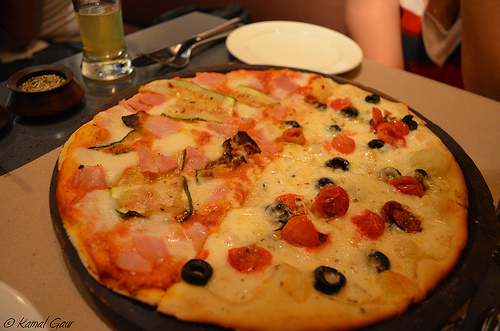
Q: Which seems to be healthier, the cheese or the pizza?
A: The cheese is healthier than the pizza.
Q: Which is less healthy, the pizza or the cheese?
A: The pizza is less healthy than the cheese.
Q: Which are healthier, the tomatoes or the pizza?
A: The tomatoes are healthier than the pizza.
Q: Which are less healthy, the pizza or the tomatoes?
A: The pizza are less healthy than the tomatoes.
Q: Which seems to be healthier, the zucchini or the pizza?
A: The zucchini is healthier than the pizza.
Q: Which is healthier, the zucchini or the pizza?
A: The zucchini is healthier than the pizza.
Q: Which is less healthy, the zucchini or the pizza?
A: The pizza is less healthy than the zucchini.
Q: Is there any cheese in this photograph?
A: Yes, there is cheese.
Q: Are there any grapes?
A: No, there are no grapes.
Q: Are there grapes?
A: No, there are no grapes.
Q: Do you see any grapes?
A: No, there are no grapes.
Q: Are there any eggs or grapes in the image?
A: No, there are no grapes or eggs.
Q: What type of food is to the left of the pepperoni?
A: The food is cheese.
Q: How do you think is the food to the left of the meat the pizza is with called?
A: The food is cheese.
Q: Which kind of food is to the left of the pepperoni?
A: The food is cheese.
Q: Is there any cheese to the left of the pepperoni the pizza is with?
A: Yes, there is cheese to the left of the pepperoni.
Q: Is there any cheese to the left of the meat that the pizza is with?
A: Yes, there is cheese to the left of the pepperoni.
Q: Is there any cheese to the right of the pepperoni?
A: No, the cheese is to the left of the pepperoni.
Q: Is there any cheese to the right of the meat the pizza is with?
A: No, the cheese is to the left of the pepperoni.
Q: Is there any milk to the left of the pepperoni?
A: No, there is cheese to the left of the pepperoni.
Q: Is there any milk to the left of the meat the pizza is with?
A: No, there is cheese to the left of the pepperoni.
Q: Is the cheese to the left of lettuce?
A: No, the cheese is to the left of the pepperoni.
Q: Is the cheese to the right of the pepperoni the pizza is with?
A: No, the cheese is to the left of the pepperoni.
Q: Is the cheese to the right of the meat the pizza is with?
A: No, the cheese is to the left of the pepperoni.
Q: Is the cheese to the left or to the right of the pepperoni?
A: The cheese is to the left of the pepperoni.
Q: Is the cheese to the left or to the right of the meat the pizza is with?
A: The cheese is to the left of the pepperoni.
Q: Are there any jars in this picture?
A: No, there are no jars.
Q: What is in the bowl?
A: The condiments are in the bowl.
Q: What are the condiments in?
A: The condiments are in the bowl.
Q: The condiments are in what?
A: The condiments are in the bowl.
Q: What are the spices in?
A: The condiments are in the bowl.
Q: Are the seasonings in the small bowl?
A: Yes, the seasonings are in the bowl.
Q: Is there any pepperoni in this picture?
A: Yes, there is pepperoni.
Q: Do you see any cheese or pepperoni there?
A: Yes, there is pepperoni.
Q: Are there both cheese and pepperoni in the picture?
A: Yes, there are both pepperoni and cheese.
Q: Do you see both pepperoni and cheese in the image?
A: Yes, there are both pepperoni and cheese.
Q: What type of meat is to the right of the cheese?
A: The meat is pepperoni.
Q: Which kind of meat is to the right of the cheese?
A: The meat is pepperoni.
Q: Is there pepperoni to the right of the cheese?
A: Yes, there is pepperoni to the right of the cheese.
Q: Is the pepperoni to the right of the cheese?
A: Yes, the pepperoni is to the right of the cheese.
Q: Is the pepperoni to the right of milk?
A: No, the pepperoni is to the right of the cheese.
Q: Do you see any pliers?
A: No, there are no pliers.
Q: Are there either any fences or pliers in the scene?
A: No, there are no pliers or fences.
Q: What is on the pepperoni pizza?
A: The toppings are on the pizza.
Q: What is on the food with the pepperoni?
A: The toppings are on the pizza.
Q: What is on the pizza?
A: The toppings are on the pizza.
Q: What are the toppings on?
A: The toppings are on the pizza.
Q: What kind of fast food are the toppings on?
A: The toppings are on the pizza.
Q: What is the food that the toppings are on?
A: The food is a pizza.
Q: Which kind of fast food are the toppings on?
A: The toppings are on the pizza.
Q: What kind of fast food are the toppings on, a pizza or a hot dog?
A: The toppings are on a pizza.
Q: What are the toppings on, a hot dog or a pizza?
A: The toppings are on a pizza.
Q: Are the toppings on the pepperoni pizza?
A: Yes, the toppings are on the pizza.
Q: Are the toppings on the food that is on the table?
A: Yes, the toppings are on the pizza.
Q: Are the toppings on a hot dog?
A: No, the toppings are on the pizza.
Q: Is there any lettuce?
A: No, there is no lettuce.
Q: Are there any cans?
A: No, there are no cans.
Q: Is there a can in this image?
A: No, there are no cans.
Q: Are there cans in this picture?
A: No, there are no cans.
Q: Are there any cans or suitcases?
A: No, there are no cans or suitcases.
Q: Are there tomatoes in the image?
A: Yes, there are tomatoes.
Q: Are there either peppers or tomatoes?
A: Yes, there are tomatoes.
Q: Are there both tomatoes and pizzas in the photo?
A: Yes, there are both tomatoes and a pizza.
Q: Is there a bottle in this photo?
A: No, there are no bottles.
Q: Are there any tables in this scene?
A: Yes, there is a table.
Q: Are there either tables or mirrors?
A: Yes, there is a table.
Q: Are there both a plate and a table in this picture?
A: Yes, there are both a table and a plate.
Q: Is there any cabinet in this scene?
A: No, there are no cabinets.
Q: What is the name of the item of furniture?
A: The piece of furniture is a table.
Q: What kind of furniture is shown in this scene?
A: The furniture is a table.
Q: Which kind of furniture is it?
A: The piece of furniture is a table.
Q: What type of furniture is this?
A: That is a table.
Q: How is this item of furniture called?
A: That is a table.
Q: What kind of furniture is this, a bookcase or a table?
A: That is a table.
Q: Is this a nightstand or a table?
A: This is a table.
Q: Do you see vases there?
A: No, there are no vases.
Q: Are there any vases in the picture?
A: No, there are no vases.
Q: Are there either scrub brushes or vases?
A: No, there are no vases or scrub brushes.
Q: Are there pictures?
A: No, there are no pictures.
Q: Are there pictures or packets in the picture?
A: No, there are no pictures or packets.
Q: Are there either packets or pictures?
A: No, there are no pictures or packets.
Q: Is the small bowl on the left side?
A: Yes, the bowl is on the left of the image.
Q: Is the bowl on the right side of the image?
A: No, the bowl is on the left of the image.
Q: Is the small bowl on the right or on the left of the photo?
A: The bowl is on the left of the image.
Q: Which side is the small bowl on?
A: The bowl is on the left of the image.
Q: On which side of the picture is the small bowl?
A: The bowl is on the left of the image.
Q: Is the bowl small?
A: Yes, the bowl is small.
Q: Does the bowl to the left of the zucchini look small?
A: Yes, the bowl is small.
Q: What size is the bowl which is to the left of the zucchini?
A: The bowl is small.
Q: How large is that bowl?
A: The bowl is small.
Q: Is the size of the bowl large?
A: No, the bowl is small.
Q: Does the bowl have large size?
A: No, the bowl is small.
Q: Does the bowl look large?
A: No, the bowl is small.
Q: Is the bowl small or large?
A: The bowl is small.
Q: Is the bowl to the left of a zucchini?
A: Yes, the bowl is to the left of a zucchini.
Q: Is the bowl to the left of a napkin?
A: No, the bowl is to the left of a zucchini.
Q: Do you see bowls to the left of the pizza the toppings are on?
A: Yes, there is a bowl to the left of the pizza.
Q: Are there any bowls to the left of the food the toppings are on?
A: Yes, there is a bowl to the left of the pizza.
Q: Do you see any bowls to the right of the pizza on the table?
A: No, the bowl is to the left of the pizza.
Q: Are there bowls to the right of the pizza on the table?
A: No, the bowl is to the left of the pizza.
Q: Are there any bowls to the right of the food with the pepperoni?
A: No, the bowl is to the left of the pizza.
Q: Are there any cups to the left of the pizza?
A: No, there is a bowl to the left of the pizza.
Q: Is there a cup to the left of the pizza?
A: No, there is a bowl to the left of the pizza.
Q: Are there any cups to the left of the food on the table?
A: No, there is a bowl to the left of the pizza.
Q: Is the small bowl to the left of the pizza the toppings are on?
A: Yes, the bowl is to the left of the pizza.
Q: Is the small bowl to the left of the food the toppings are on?
A: Yes, the bowl is to the left of the pizza.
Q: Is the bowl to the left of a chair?
A: No, the bowl is to the left of the pizza.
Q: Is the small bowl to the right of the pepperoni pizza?
A: No, the bowl is to the left of the pizza.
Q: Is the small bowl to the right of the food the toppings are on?
A: No, the bowl is to the left of the pizza.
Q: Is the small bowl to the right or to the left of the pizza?
A: The bowl is to the left of the pizza.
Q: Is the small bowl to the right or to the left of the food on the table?
A: The bowl is to the left of the pizza.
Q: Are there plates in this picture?
A: Yes, there is a plate.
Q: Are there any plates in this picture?
A: Yes, there is a plate.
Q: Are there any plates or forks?
A: Yes, there is a plate.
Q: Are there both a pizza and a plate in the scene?
A: Yes, there are both a plate and a pizza.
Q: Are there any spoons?
A: No, there are no spoons.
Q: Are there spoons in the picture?
A: No, there are no spoons.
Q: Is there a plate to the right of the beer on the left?
A: Yes, there is a plate to the right of the beer.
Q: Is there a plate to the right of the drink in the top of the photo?
A: Yes, there is a plate to the right of the beer.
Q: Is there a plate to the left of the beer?
A: No, the plate is to the right of the beer.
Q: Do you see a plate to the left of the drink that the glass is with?
A: No, the plate is to the right of the beer.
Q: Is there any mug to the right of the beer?
A: No, there is a plate to the right of the beer.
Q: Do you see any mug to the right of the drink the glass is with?
A: No, there is a plate to the right of the beer.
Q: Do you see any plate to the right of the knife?
A: Yes, there is a plate to the right of the knife.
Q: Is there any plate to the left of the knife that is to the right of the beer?
A: No, the plate is to the right of the knife.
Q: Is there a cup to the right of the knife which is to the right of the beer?
A: No, there is a plate to the right of the knife.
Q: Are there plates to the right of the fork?
A: Yes, there is a plate to the right of the fork.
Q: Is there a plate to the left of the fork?
A: No, the plate is to the right of the fork.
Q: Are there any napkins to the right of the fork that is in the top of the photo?
A: No, there is a plate to the right of the fork.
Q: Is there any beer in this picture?
A: Yes, there is beer.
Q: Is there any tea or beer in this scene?
A: Yes, there is beer.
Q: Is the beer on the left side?
A: Yes, the beer is on the left of the image.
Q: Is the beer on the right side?
A: No, the beer is on the left of the image.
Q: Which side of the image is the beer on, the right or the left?
A: The beer is on the left of the image.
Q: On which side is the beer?
A: The beer is on the left of the image.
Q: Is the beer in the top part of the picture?
A: Yes, the beer is in the top of the image.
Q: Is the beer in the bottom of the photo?
A: No, the beer is in the top of the image.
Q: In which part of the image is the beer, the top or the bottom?
A: The beer is in the top of the image.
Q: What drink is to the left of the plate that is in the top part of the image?
A: The drink is beer.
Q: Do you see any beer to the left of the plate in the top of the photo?
A: Yes, there is beer to the left of the plate.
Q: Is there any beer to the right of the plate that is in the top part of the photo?
A: No, the beer is to the left of the plate.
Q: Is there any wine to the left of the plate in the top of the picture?
A: No, there is beer to the left of the plate.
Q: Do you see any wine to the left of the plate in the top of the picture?
A: No, there is beer to the left of the plate.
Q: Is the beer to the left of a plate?
A: Yes, the beer is to the left of a plate.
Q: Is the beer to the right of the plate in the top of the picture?
A: No, the beer is to the left of the plate.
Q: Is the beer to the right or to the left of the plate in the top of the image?
A: The beer is to the left of the plate.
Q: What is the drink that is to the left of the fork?
A: The drink is beer.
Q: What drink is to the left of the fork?
A: The drink is beer.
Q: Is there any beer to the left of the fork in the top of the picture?
A: Yes, there is beer to the left of the fork.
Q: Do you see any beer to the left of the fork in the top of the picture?
A: Yes, there is beer to the left of the fork.